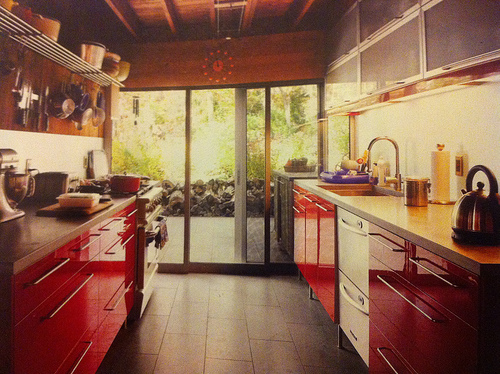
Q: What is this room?
A: Kitchen.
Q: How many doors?
A: Two.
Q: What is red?
A: Cabinets.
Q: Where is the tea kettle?
A: On the right.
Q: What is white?
A: Walls.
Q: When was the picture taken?
A: Daytime.